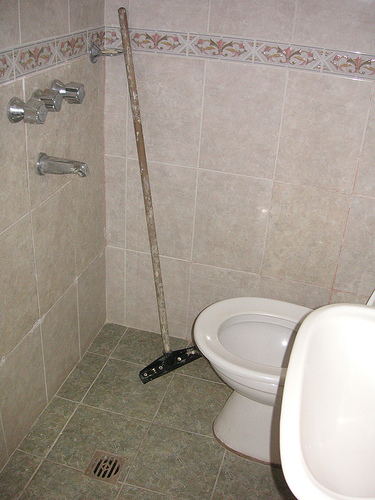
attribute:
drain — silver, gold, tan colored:
[84, 449, 126, 483]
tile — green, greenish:
[82, 359, 173, 422]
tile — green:
[128, 422, 225, 495]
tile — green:
[18, 398, 77, 459]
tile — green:
[88, 322, 128, 358]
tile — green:
[20, 460, 123, 499]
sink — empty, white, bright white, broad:
[280, 300, 373, 498]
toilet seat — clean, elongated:
[192, 296, 314, 381]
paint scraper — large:
[118, 8, 201, 384]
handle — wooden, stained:
[119, 6, 176, 352]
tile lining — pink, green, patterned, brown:
[1, 27, 374, 85]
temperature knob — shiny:
[8, 98, 48, 123]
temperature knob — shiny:
[53, 80, 86, 103]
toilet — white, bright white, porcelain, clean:
[193, 272, 373, 467]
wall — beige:
[1, 0, 104, 469]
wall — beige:
[102, 3, 372, 343]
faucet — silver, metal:
[38, 154, 88, 175]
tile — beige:
[197, 60, 287, 174]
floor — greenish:
[12, 321, 296, 500]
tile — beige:
[276, 67, 370, 197]